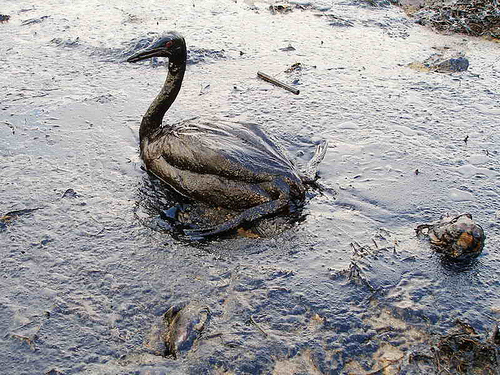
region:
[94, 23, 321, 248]
duck in the oil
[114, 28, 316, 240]
bird stuck in the muck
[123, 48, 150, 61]
beak of the bird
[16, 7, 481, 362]
debris in the muck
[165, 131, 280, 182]
wing of the bird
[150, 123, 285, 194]
body of the bird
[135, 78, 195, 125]
neck of the bird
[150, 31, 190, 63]
head of the bird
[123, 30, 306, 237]
bird covered in muck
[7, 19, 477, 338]
ripples in the muck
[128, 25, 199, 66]
head of a bird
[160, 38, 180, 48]
eye of a bird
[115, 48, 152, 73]
peck of a bird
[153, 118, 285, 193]
wing of a bird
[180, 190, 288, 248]
leg of a bird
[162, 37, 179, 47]
an eye of a bird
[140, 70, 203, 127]
neck of a bird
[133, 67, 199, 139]
a neck of a bird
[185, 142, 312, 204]
feather of a bird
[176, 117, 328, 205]
body of a bird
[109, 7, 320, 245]
this is a bird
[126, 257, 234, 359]
this is mud in the ground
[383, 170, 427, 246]
this is mud in the ground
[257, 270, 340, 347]
this is mud in the ground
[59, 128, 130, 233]
this is mud in the ground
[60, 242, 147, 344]
this is mud in the ground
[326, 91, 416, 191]
this is mud in the ground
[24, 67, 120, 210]
this is mud in the ground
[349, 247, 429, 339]
this is mud in the ground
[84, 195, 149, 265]
this is mud in the ground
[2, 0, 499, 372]
Oil has contaminated the water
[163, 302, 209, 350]
A rock in the oily water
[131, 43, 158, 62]
The beak of the bird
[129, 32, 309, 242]
A bird soaked in oily water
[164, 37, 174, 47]
The left eye of the bird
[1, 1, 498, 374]
The water is oily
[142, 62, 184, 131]
The bird has a long neck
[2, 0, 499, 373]
An oil spill beneath the bird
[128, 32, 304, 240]
The bird is sitting in an oil spill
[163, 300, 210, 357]
An oily rock next to the bird